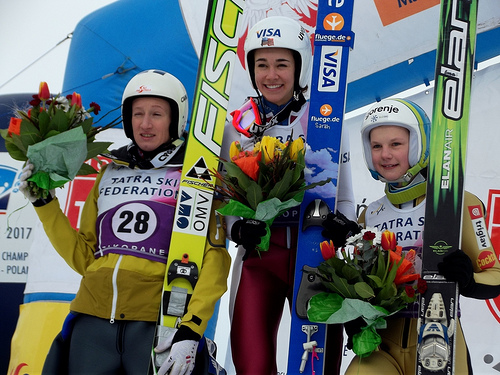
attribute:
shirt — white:
[366, 202, 423, 244]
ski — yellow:
[149, 0, 249, 375]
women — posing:
[227, 30, 352, 365]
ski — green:
[415, 0, 475, 374]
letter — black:
[107, 173, 126, 185]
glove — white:
[146, 321, 201, 366]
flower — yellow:
[255, 129, 278, 159]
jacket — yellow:
[75, 147, 223, 305]